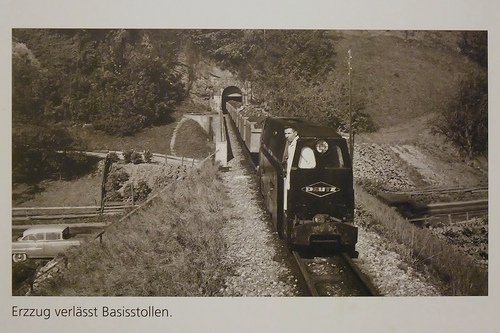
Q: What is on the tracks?
A: The train.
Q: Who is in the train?
A: The man.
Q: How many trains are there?
A: One.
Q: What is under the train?
A: Tracks.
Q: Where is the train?
A: On the tracks.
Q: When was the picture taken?
A: Daytime.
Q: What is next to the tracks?
A: Gravel.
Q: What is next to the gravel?
A: The train tracks.